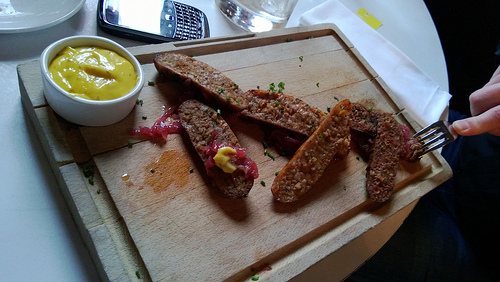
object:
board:
[135, 154, 240, 254]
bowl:
[37, 34, 148, 130]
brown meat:
[153, 50, 425, 208]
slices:
[156, 53, 416, 209]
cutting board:
[16, 22, 456, 282]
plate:
[1, 0, 87, 34]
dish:
[46, 39, 142, 105]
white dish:
[36, 34, 142, 127]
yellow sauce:
[53, 37, 136, 99]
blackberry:
[94, 1, 212, 43]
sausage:
[153, 50, 419, 207]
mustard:
[42, 37, 140, 100]